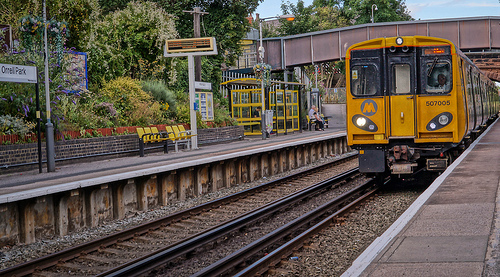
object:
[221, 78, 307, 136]
area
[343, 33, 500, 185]
train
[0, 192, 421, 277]
gravel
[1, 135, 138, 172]
wall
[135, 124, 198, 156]
bench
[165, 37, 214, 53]
sign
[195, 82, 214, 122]
sign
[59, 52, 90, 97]
sign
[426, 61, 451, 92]
window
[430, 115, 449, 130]
light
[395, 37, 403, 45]
light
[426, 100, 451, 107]
numbers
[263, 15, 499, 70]
bridge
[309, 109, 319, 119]
shirt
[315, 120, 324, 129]
pants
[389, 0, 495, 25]
sky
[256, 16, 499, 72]
walkway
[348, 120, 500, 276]
platform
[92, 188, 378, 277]
rail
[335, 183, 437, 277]
line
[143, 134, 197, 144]
seats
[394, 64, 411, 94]
window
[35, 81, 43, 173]
pole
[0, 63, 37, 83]
sign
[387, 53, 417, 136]
door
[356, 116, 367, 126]
headlight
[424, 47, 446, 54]
destination sign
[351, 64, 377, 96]
window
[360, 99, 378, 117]
decal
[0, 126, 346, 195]
sidewalk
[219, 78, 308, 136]
building